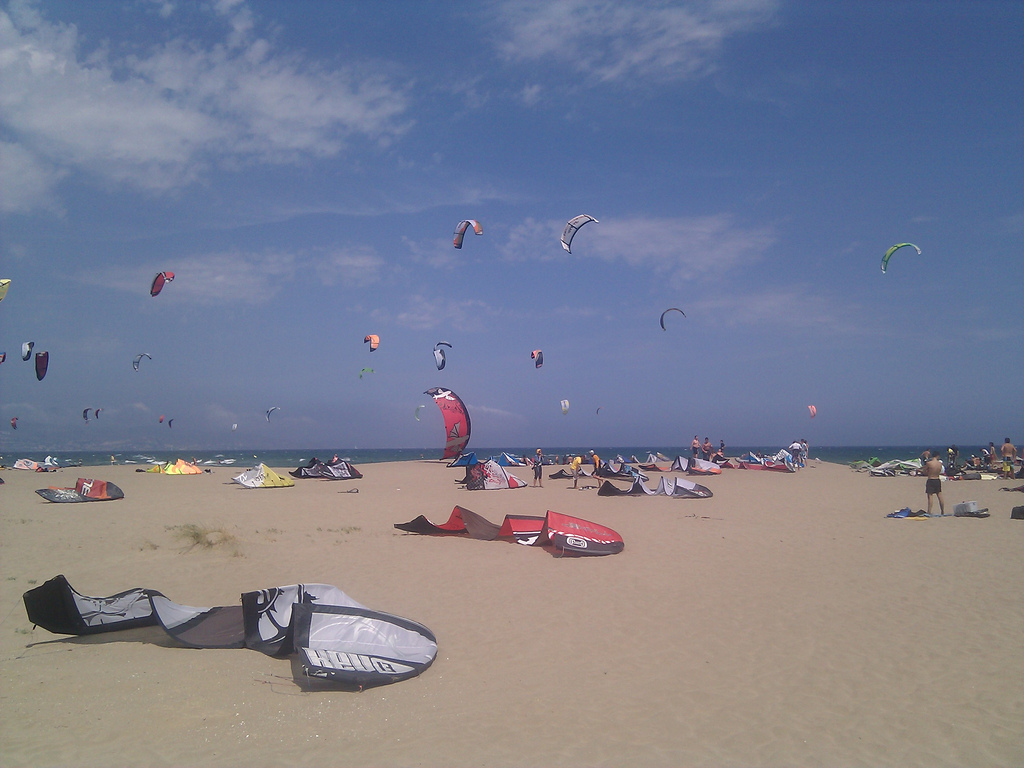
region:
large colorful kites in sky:
[78, 183, 212, 314]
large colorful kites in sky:
[397, 212, 493, 293]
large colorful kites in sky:
[73, 212, 178, 305]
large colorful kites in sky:
[20, 335, 139, 437]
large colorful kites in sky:
[263, 303, 426, 384]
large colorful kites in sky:
[471, 127, 672, 296]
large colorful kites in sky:
[476, 306, 587, 408]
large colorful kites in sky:
[611, 259, 695, 337]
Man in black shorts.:
[918, 446, 950, 519]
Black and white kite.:
[24, 567, 442, 698]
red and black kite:
[396, 501, 627, 555]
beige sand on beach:
[735, 623, 936, 699]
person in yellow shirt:
[565, 452, 589, 487]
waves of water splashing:
[118, 449, 153, 468]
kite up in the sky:
[365, 323, 384, 359]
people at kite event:
[756, 436, 811, 468]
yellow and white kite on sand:
[232, 453, 289, 492]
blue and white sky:
[114, 34, 514, 194]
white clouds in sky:
[17, 25, 499, 191]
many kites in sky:
[114, 171, 1015, 402]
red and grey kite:
[383, 502, 678, 598]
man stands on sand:
[871, 429, 958, 534]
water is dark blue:
[295, 429, 400, 469]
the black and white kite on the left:
[19, 542, 444, 697]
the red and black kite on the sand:
[387, 497, 616, 551]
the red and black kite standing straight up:
[419, 386, 470, 462]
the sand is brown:
[0, 462, 1018, 760]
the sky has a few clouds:
[0, 0, 1018, 441]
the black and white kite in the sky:
[554, 204, 592, 249]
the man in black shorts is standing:
[918, 441, 939, 512]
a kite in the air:
[546, 213, 600, 256]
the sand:
[666, 614, 788, 732]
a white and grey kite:
[228, 571, 438, 686]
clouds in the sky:
[227, 70, 348, 154]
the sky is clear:
[778, 125, 873, 205]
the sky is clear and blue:
[743, 143, 846, 214]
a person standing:
[922, 447, 958, 511]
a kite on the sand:
[73, 469, 135, 505]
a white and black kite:
[0, 553, 459, 713]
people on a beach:
[2, 367, 1011, 766]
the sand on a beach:
[600, 554, 905, 717]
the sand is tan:
[675, 554, 830, 716]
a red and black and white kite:
[386, 509, 630, 574]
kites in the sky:
[3, 162, 962, 457]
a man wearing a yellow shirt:
[561, 446, 591, 491]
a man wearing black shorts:
[912, 440, 950, 520]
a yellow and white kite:
[157, 443, 216, 479]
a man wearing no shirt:
[909, 439, 948, 516]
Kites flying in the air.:
[0, 187, 944, 447]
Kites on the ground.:
[32, 442, 966, 702]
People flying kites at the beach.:
[501, 421, 1023, 524]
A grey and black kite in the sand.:
[22, 569, 466, 700]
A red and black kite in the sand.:
[394, 495, 661, 560]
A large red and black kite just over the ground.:
[416, 380, 481, 469]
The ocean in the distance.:
[16, 436, 1022, 471]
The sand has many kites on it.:
[25, 442, 1022, 680]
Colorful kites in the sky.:
[9, 200, 952, 422]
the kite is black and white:
[22, 572, 438, 691]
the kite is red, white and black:
[392, 503, 624, 557]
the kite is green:
[879, 234, 925, 277]